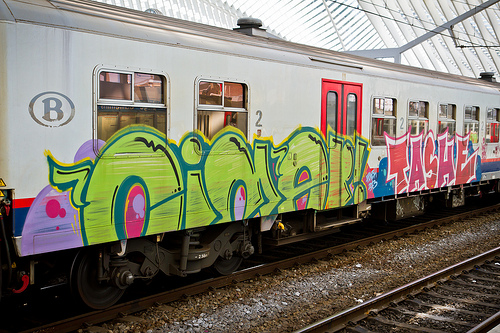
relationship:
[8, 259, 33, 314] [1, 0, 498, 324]
machinery hanging under train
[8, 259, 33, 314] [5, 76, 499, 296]
machinery under train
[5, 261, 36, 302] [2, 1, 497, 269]
machinery under train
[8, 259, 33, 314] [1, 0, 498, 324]
machinery under train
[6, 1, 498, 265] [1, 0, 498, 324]
side of train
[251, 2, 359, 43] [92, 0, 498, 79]
light through ceiling